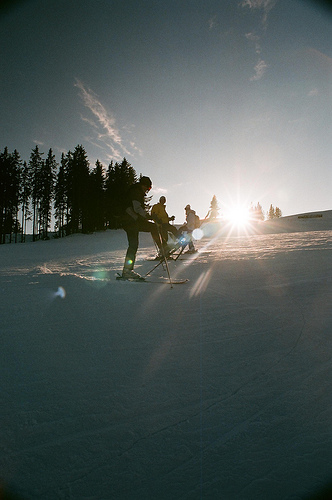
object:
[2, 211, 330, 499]
snow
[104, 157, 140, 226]
tree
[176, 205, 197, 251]
person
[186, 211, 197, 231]
jacket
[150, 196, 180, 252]
person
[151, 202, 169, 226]
jacket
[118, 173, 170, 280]
people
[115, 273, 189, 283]
skis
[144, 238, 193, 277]
ski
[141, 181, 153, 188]
goggles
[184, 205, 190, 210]
hat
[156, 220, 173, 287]
ski pole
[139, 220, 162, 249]
leg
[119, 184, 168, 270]
outfit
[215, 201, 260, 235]
sun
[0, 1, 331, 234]
sky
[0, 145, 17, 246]
pine trees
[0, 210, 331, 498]
hill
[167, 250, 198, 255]
skis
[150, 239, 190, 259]
skis